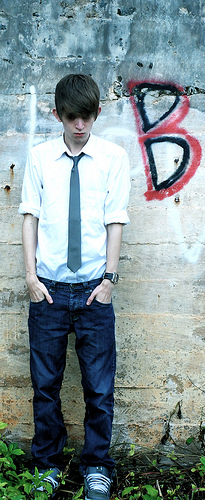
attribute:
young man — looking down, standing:
[19, 74, 130, 500]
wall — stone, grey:
[0, 0, 204, 499]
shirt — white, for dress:
[19, 132, 130, 283]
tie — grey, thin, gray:
[65, 153, 85, 274]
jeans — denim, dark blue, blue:
[28, 277, 116, 470]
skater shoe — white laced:
[31, 468, 64, 500]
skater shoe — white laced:
[81, 465, 111, 500]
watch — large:
[101, 272, 120, 285]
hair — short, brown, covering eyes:
[54, 74, 100, 122]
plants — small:
[122, 483, 160, 499]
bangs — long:
[61, 90, 95, 115]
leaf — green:
[120, 486, 135, 496]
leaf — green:
[143, 485, 159, 499]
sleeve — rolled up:
[20, 150, 44, 219]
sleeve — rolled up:
[103, 143, 131, 226]